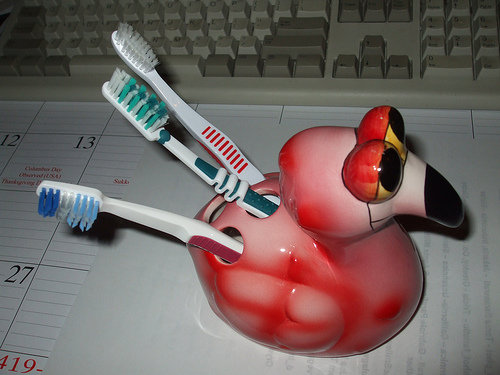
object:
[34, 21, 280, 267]
toothbrushes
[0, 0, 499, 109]
keyboard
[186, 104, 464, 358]
holder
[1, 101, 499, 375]
calendar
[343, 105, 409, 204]
eyes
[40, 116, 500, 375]
paper